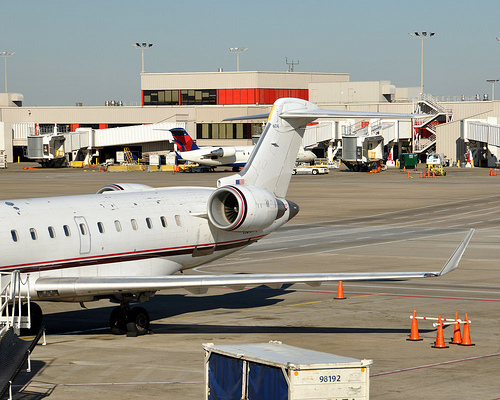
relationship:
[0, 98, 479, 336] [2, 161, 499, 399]
plane on tarmac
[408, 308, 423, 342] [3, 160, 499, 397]
cone on ground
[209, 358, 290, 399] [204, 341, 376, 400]
luggage on cart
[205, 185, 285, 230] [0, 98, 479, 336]
engine on plane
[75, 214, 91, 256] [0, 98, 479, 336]
door on plane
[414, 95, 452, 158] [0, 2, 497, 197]
stairs in background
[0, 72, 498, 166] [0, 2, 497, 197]
building in background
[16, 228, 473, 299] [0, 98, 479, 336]
wing on plane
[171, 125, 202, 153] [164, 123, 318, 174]
tail of plane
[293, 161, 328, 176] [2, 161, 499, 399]
vehicle on tarmac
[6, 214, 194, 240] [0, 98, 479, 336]
windows on plane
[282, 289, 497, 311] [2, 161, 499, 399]
lines on tarmac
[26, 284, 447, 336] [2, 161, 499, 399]
shadow on tarmac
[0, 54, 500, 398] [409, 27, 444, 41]
airport has lights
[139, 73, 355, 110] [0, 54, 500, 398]
terminal at airport